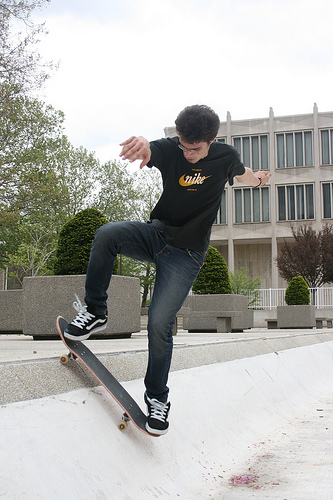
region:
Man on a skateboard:
[54, 101, 271, 436]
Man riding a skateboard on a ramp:
[55, 104, 270, 438]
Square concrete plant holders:
[19, 273, 142, 336]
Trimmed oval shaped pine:
[54, 207, 118, 275]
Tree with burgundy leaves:
[275, 221, 331, 305]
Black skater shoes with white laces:
[64, 293, 171, 435]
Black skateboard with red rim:
[54, 313, 160, 440]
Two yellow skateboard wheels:
[59, 352, 126, 430]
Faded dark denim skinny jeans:
[84, 217, 204, 402]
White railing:
[187, 286, 330, 311]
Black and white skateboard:
[42, 305, 173, 442]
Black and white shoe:
[57, 292, 115, 353]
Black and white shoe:
[140, 376, 174, 433]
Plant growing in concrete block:
[270, 256, 320, 333]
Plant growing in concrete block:
[180, 248, 251, 337]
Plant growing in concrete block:
[23, 215, 159, 360]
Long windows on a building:
[274, 130, 322, 178]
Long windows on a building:
[273, 181, 320, 223]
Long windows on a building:
[228, 132, 274, 179]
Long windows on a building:
[318, 122, 332, 168]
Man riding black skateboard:
[64, 104, 272, 437]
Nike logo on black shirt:
[174, 171, 216, 194]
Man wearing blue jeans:
[62, 104, 272, 435]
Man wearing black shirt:
[63, 103, 273, 437]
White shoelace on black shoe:
[66, 292, 92, 327]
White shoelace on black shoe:
[146, 392, 167, 422]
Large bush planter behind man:
[19, 207, 143, 334]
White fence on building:
[238, 287, 332, 309]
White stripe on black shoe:
[86, 315, 107, 331]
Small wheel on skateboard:
[57, 354, 68, 365]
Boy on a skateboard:
[55, 102, 271, 438]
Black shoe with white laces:
[141, 390, 172, 436]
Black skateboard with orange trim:
[54, 314, 162, 438]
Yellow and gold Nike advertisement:
[177, 164, 213, 193]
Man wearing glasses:
[173, 103, 221, 163]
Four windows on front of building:
[274, 128, 316, 170]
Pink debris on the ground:
[193, 430, 289, 497]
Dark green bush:
[284, 273, 311, 307]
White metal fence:
[263, 286, 277, 310]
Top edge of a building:
[283, 112, 312, 118]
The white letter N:
[180, 170, 198, 187]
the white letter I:
[187, 168, 201, 187]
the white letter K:
[193, 169, 203, 188]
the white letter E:
[199, 175, 207, 185]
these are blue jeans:
[54, 196, 224, 418]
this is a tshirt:
[122, 119, 252, 272]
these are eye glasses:
[170, 128, 220, 160]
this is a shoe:
[52, 291, 123, 353]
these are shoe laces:
[60, 288, 100, 329]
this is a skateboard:
[42, 295, 166, 443]